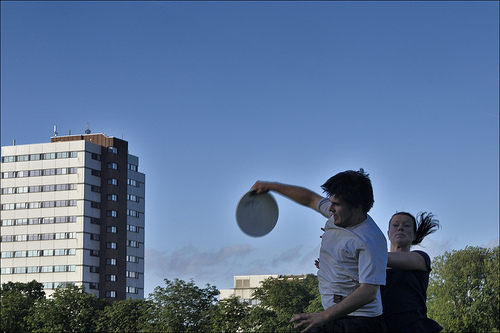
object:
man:
[250, 167, 387, 332]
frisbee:
[236, 188, 280, 237]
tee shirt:
[317, 198, 389, 319]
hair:
[321, 168, 375, 213]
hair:
[389, 211, 443, 246]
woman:
[314, 211, 442, 332]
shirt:
[362, 250, 443, 333]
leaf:
[59, 294, 109, 316]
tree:
[0, 282, 39, 333]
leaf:
[8, 297, 33, 307]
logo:
[333, 294, 343, 304]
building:
[0, 122, 146, 304]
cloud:
[147, 244, 315, 275]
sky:
[2, 2, 499, 301]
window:
[64, 216, 72, 222]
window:
[64, 249, 70, 255]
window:
[4, 200, 57, 235]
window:
[106, 242, 118, 250]